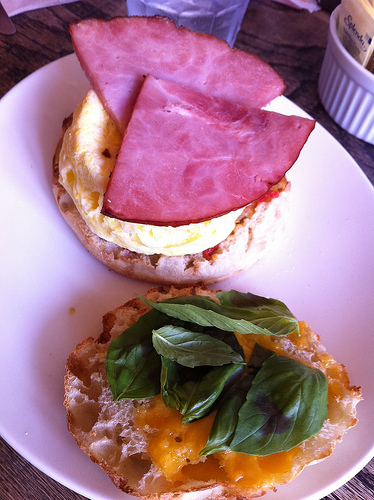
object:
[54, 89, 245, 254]
egg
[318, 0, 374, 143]
bowl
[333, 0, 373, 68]
packets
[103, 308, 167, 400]
spinach leaf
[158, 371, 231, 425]
spinach leaf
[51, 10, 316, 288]
sandwich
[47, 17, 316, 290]
english muffin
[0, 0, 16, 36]
knife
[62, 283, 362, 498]
bagel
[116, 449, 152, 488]
whole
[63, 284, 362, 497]
sandwich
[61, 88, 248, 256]
egg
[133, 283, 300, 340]
leaf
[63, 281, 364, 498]
english muffin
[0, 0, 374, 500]
table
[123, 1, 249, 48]
drinking glass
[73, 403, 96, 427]
hole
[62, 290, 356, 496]
muffin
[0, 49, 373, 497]
plate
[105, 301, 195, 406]
leaf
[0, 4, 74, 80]
wood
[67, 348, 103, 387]
hole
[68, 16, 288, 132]
ham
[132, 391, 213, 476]
jam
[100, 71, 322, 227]
bacon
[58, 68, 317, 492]
english muffins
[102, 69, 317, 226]
ham meat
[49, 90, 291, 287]
biscuit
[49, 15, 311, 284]
sandwich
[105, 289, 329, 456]
spinach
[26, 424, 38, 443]
crumb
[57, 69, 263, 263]
bottom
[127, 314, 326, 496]
cheese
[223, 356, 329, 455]
leaf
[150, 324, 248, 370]
leaf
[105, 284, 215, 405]
leaves